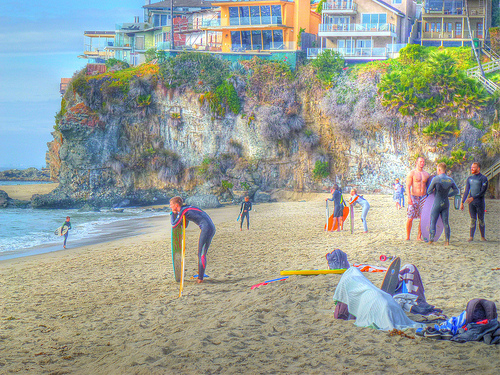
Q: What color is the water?
A: Blue.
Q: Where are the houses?
A: On the cliff.